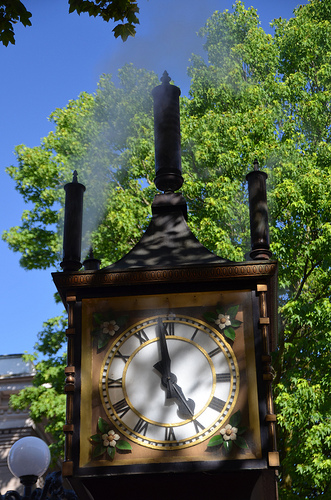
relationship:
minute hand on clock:
[164, 374, 198, 419] [86, 295, 254, 413]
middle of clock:
[152, 400, 184, 450] [237, 436, 284, 483]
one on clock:
[190, 322, 200, 347] [237, 436, 284, 483]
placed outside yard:
[75, 155, 266, 270] [290, 485, 317, 499]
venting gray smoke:
[62, 191, 108, 264] [97, 66, 141, 201]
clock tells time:
[237, 436, 284, 483] [142, 323, 180, 337]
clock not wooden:
[237, 436, 284, 483] [27, 145, 310, 405]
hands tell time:
[162, 312, 195, 422] [142, 323, 180, 337]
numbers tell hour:
[116, 332, 242, 420] [164, 374, 198, 419]